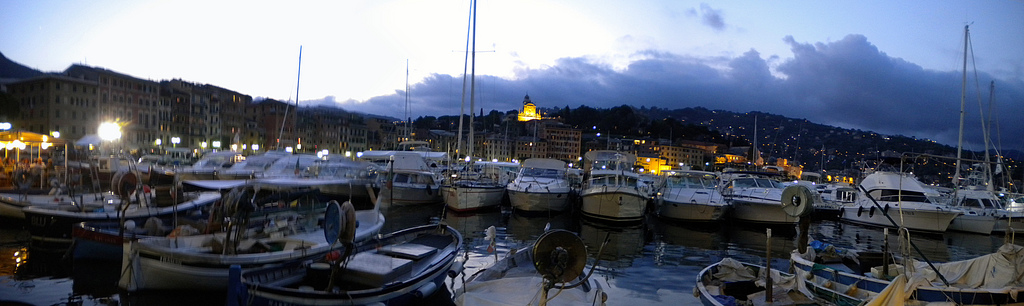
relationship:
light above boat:
[510, 94, 547, 125] [495, 154, 586, 226]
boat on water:
[777, 245, 1020, 302] [384, 206, 1020, 300]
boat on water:
[775, 234, 1020, 302] [243, 196, 1019, 302]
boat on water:
[6, 182, 225, 252] [243, 196, 1019, 302]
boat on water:
[172, 146, 270, 207] [338, 198, 1006, 302]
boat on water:
[375, 154, 440, 206] [367, 189, 804, 302]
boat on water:
[513, 155, 574, 218] [189, 182, 794, 303]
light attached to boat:
[67, 100, 145, 167] [6, 177, 248, 236]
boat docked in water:
[565, 158, 652, 239] [24, 128, 977, 275]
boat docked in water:
[638, 163, 736, 241] [1, 95, 1006, 292]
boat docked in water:
[709, 175, 831, 247] [1, 95, 1006, 292]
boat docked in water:
[843, 163, 984, 241] [7, 111, 1010, 302]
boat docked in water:
[495, 114, 580, 215] [317, 191, 1015, 302]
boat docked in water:
[431, 0, 508, 216] [243, 196, 1019, 302]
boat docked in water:
[375, 154, 440, 206] [243, 196, 1019, 302]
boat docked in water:
[122, 200, 391, 289] [243, 196, 1019, 302]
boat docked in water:
[230, 219, 468, 302] [168, 182, 1020, 303]